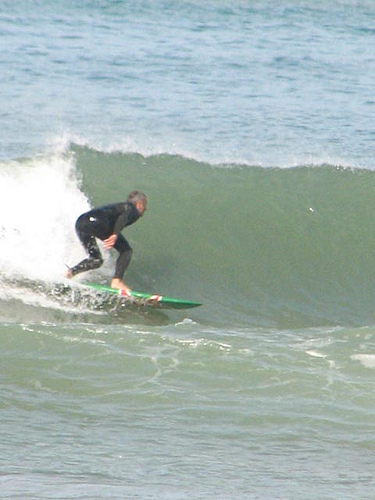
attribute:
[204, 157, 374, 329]
water — green, murky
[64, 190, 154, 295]
surfer — black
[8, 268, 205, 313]
surfboard — green, red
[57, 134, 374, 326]
wave — green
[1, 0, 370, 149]
water — clear, blue, nice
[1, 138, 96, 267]
foam — white, awesome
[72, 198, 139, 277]
wetsuit — black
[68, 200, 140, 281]
wetsuit — black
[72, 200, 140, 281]
clothing — dark